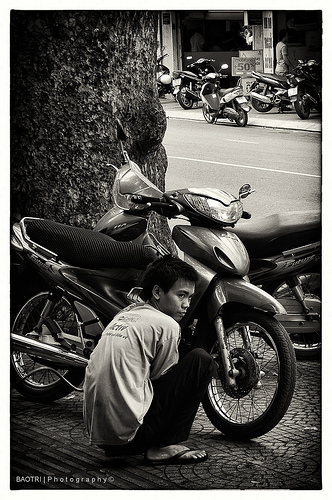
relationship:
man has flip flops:
[85, 249, 222, 467] [142, 440, 210, 467]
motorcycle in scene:
[17, 177, 297, 447] [12, 11, 327, 492]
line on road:
[179, 154, 285, 180] [168, 119, 323, 227]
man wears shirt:
[85, 249, 222, 467] [76, 299, 186, 452]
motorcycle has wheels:
[17, 120, 297, 446] [9, 278, 305, 441]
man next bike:
[85, 249, 222, 467] [88, 113, 323, 363]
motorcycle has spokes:
[17, 177, 297, 447] [216, 327, 272, 403]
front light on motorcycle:
[179, 188, 247, 224] [17, 177, 297, 447]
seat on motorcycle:
[12, 209, 161, 278] [17, 177, 297, 447]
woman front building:
[273, 34, 293, 83] [154, 11, 321, 75]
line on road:
[161, 152, 322, 181] [168, 119, 323, 227]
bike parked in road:
[198, 73, 253, 128] [168, 119, 323, 227]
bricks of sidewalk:
[239, 448, 314, 490] [46, 323, 323, 488]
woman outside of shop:
[263, 21, 308, 83] [161, 15, 306, 105]